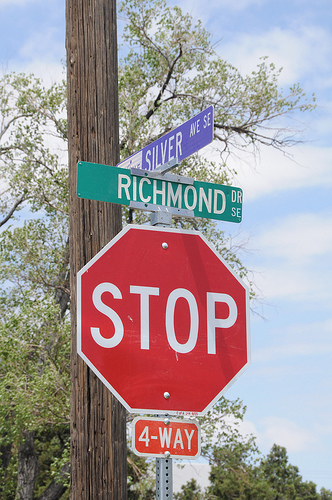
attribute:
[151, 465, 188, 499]
post — cracked, tall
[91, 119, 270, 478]
signs — blue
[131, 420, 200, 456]
sign — red, metal, octagonal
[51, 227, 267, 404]
sign — red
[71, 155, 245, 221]
street sign — green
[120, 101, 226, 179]
street sign — blue, purple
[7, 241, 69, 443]
trees — green, waving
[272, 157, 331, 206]
clouds — white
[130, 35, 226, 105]
tree — large, green, standing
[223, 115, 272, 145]
branch — dying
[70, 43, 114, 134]
pole — brown, straight, wood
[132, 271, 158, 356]
letters — white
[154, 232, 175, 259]
bolt — silver, round